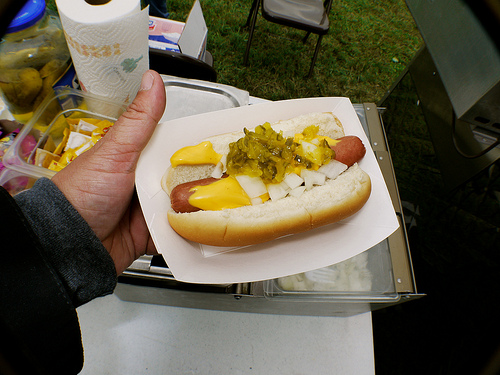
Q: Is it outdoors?
A: Yes, it is outdoors.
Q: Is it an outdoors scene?
A: Yes, it is outdoors.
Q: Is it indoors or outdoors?
A: It is outdoors.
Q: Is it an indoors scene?
A: No, it is outdoors.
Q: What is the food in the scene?
A: The food is a bun.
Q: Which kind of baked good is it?
A: The food is a bun.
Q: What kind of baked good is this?
A: This is a bun.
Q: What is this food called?
A: This is a bun.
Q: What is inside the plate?
A: The bun is inside the plate.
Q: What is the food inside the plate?
A: The food is a bun.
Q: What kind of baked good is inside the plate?
A: The food is a bun.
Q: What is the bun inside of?
A: The bun is inside the plate.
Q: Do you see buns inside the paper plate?
A: Yes, there is a bun inside the plate.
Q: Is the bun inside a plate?
A: Yes, the bun is inside a plate.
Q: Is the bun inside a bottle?
A: No, the bun is inside a plate.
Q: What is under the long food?
A: The bun is under the hot dog.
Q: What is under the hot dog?
A: The bun is under the hot dog.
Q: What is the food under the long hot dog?
A: The food is a bun.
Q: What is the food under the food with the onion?
A: The food is a bun.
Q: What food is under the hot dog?
A: The food is a bun.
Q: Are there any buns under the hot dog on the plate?
A: Yes, there is a bun under the hot dog.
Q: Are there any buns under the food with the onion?
A: Yes, there is a bun under the hot dog.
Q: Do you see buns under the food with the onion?
A: Yes, there is a bun under the hot dog.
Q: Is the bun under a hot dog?
A: Yes, the bun is under a hot dog.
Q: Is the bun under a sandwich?
A: No, the bun is under a hot dog.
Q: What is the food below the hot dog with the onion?
A: The food is a bun.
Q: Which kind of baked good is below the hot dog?
A: The food is a bun.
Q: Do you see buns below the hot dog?
A: Yes, there is a bun below the hot dog.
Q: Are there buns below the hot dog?
A: Yes, there is a bun below the hot dog.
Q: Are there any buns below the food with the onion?
A: Yes, there is a bun below the hot dog.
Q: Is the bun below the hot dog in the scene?
A: Yes, the bun is below the hot dog.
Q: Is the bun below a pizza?
A: No, the bun is below the hot dog.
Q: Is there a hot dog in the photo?
A: Yes, there is a hot dog.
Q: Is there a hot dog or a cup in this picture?
A: Yes, there is a hot dog.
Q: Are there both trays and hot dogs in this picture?
A: Yes, there are both a hot dog and a tray.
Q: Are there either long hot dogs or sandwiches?
A: Yes, there is a long hot dog.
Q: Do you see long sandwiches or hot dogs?
A: Yes, there is a long hot dog.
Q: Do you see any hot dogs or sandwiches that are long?
A: Yes, the hot dog is long.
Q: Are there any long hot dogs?
A: Yes, there is a long hot dog.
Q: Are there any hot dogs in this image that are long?
A: Yes, there is a hot dog that is long.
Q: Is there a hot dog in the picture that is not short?
A: Yes, there is a long hot dog.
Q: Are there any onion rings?
A: No, there are no onion rings.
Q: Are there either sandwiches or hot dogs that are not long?
A: No, there is a hot dog but it is long.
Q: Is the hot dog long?
A: Yes, the hot dog is long.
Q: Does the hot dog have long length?
A: Yes, the hot dog is long.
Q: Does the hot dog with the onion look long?
A: Yes, the hot dog is long.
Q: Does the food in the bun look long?
A: Yes, the hot dog is long.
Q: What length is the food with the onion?
A: The hot dog is long.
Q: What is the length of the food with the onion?
A: The hot dog is long.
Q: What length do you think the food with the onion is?
A: The hot dog is long.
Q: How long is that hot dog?
A: The hot dog is long.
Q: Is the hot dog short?
A: No, the hot dog is long.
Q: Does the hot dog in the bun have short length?
A: No, the hot dog is long.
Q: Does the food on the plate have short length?
A: No, the hot dog is long.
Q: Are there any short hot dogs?
A: No, there is a hot dog but it is long.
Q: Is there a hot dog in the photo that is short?
A: No, there is a hot dog but it is long.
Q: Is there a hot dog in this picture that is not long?
A: No, there is a hot dog but it is long.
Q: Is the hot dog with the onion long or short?
A: The hot dog is long.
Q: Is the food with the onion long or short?
A: The hot dog is long.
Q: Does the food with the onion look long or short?
A: The hot dog is long.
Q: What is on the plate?
A: The hot dog is on the plate.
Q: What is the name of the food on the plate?
A: The food is a hot dog.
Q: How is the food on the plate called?
A: The food is a hot dog.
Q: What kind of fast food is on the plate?
A: The food is a hot dog.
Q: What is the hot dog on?
A: The hot dog is on the plate.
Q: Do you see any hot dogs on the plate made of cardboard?
A: Yes, there is a hot dog on the plate.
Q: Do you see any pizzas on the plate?
A: No, there is a hot dog on the plate.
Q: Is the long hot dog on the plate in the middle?
A: Yes, the hot dog is on the plate.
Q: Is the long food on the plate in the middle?
A: Yes, the hot dog is on the plate.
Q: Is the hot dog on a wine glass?
A: No, the hot dog is on the plate.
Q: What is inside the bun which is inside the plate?
A: The hot dog is inside the bun.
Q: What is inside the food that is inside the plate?
A: The hot dog is inside the bun.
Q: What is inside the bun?
A: The hot dog is inside the bun.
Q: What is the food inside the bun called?
A: The food is a hot dog.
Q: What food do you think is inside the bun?
A: The food is a hot dog.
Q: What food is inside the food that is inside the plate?
A: The food is a hot dog.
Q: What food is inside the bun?
A: The food is a hot dog.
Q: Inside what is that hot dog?
A: The hot dog is inside the bun.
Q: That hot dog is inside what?
A: The hot dog is inside the bun.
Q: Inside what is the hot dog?
A: The hot dog is inside the bun.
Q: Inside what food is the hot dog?
A: The hot dog is inside the bun.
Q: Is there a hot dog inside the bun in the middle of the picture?
A: Yes, there is a hot dog inside the bun.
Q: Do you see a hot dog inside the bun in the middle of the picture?
A: Yes, there is a hot dog inside the bun.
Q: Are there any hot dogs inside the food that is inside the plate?
A: Yes, there is a hot dog inside the bun.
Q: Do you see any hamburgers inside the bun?
A: No, there is a hot dog inside the bun.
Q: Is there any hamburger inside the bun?
A: No, there is a hot dog inside the bun.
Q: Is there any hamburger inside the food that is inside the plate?
A: No, there is a hot dog inside the bun.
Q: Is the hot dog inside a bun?
A: Yes, the hot dog is inside a bun.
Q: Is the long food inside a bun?
A: Yes, the hot dog is inside a bun.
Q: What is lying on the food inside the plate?
A: The hot dog is lying on the bun.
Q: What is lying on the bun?
A: The hot dog is lying on the bun.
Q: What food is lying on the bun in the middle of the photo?
A: The food is a hot dog.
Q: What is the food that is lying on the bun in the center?
A: The food is a hot dog.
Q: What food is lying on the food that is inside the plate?
A: The food is a hot dog.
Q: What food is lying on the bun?
A: The food is a hot dog.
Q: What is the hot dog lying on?
A: The hot dog is lying on the bun.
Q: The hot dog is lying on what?
A: The hot dog is lying on the bun.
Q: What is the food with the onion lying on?
A: The hot dog is lying on the bun.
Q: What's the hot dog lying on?
A: The hot dog is lying on the bun.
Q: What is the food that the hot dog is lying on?
A: The food is a bun.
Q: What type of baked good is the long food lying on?
A: The hot dog is lying on the bun.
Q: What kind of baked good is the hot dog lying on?
A: The hot dog is lying on the bun.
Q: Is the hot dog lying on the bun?
A: Yes, the hot dog is lying on the bun.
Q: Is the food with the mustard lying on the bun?
A: Yes, the hot dog is lying on the bun.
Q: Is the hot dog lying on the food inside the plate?
A: Yes, the hot dog is lying on the bun.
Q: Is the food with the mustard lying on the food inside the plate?
A: Yes, the hot dog is lying on the bun.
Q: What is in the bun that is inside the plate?
A: The hot dog is in the bun.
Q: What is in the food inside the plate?
A: The hot dog is in the bun.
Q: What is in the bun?
A: The hot dog is in the bun.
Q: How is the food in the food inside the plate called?
A: The food is a hot dog.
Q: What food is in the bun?
A: The food is a hot dog.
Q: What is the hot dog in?
A: The hot dog is in the bun.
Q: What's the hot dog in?
A: The hot dog is in the bun.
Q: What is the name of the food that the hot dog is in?
A: The food is a bun.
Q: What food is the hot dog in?
A: The hot dog is in the bun.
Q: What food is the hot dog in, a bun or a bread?
A: The hot dog is in a bun.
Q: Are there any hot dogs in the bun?
A: Yes, there is a hot dog in the bun.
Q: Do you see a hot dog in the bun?
A: Yes, there is a hot dog in the bun.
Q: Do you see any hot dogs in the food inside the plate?
A: Yes, there is a hot dog in the bun.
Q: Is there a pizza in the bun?
A: No, there is a hot dog in the bun.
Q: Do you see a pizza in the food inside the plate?
A: No, there is a hot dog in the bun.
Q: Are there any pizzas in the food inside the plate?
A: No, there is a hot dog in the bun.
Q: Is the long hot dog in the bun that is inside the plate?
A: Yes, the hot dog is in the bun.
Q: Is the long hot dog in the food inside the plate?
A: Yes, the hot dog is in the bun.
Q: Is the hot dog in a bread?
A: No, the hot dog is in the bun.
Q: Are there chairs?
A: Yes, there is a chair.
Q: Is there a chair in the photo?
A: Yes, there is a chair.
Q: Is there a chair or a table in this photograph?
A: Yes, there is a chair.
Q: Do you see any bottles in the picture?
A: No, there are no bottles.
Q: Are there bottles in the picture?
A: No, there are no bottles.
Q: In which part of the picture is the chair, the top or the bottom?
A: The chair is in the top of the image.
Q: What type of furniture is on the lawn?
A: The piece of furniture is a chair.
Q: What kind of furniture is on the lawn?
A: The piece of furniture is a chair.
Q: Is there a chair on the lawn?
A: Yes, there is a chair on the lawn.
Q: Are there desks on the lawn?
A: No, there is a chair on the lawn.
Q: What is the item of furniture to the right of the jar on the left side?
A: The piece of furniture is a chair.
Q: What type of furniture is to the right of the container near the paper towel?
A: The piece of furniture is a chair.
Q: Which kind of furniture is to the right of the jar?
A: The piece of furniture is a chair.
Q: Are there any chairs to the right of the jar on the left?
A: Yes, there is a chair to the right of the jar.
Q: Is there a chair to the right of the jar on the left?
A: Yes, there is a chair to the right of the jar.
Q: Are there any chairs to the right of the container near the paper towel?
A: Yes, there is a chair to the right of the jar.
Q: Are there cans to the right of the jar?
A: No, there is a chair to the right of the jar.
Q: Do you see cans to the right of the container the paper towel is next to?
A: No, there is a chair to the right of the jar.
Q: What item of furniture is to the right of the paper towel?
A: The piece of furniture is a chair.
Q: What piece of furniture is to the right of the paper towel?
A: The piece of furniture is a chair.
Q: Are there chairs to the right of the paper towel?
A: Yes, there is a chair to the right of the paper towel.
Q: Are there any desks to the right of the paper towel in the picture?
A: No, there is a chair to the right of the paper towel.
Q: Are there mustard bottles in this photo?
A: No, there are no mustard bottles.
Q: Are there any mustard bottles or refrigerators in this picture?
A: No, there are no mustard bottles or refrigerators.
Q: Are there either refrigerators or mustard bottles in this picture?
A: No, there are no mustard bottles or refrigerators.